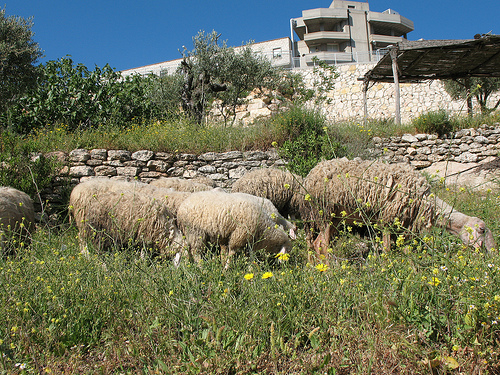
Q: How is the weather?
A: It is clear.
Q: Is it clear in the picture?
A: Yes, it is clear.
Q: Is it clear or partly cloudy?
A: It is clear.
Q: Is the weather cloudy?
A: No, it is clear.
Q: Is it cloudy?
A: No, it is clear.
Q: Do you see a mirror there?
A: No, there are no mirrors.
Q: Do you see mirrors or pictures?
A: No, there are no mirrors or pictures.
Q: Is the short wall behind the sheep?
A: Yes, the wall is behind the sheep.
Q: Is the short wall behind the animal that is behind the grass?
A: Yes, the wall is behind the sheep.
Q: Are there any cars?
A: No, there are no cars.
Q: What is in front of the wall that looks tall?
A: The trees are in front of the wall.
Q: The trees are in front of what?
A: The trees are in front of the wall.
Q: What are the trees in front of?
A: The trees are in front of the wall.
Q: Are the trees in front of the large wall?
A: Yes, the trees are in front of the wall.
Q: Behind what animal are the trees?
A: The trees are behind the sheep.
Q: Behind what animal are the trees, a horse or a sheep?
A: The trees are behind a sheep.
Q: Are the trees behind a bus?
A: No, the trees are behind the sheep.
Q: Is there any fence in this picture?
A: Yes, there is a fence.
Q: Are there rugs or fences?
A: Yes, there is a fence.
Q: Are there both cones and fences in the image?
A: No, there is a fence but no cones.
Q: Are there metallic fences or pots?
A: Yes, there is a metal fence.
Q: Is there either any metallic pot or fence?
A: Yes, there is a metal fence.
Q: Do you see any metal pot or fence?
A: Yes, there is a metal fence.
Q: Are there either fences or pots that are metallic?
A: Yes, the fence is metallic.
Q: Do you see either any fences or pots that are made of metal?
A: Yes, the fence is made of metal.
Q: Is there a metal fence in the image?
A: Yes, there is a metal fence.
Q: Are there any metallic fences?
A: Yes, there is a metal fence.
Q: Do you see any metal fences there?
A: Yes, there is a metal fence.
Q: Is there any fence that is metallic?
A: Yes, there is a fence that is metallic.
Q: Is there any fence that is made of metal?
A: Yes, there is a fence that is made of metal.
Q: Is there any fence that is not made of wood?
A: Yes, there is a fence that is made of metal.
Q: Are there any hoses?
A: No, there are no hoses.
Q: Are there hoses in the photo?
A: No, there are no hoses.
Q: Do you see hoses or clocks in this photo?
A: No, there are no hoses or clocks.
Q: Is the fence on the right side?
A: Yes, the fence is on the right of the image.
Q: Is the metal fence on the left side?
A: No, the fence is on the right of the image.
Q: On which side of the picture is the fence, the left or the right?
A: The fence is on the right of the image.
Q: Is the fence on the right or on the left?
A: The fence is on the right of the image.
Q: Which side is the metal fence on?
A: The fence is on the right of the image.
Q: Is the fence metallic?
A: Yes, the fence is metallic.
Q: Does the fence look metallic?
A: Yes, the fence is metallic.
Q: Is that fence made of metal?
A: Yes, the fence is made of metal.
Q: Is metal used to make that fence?
A: Yes, the fence is made of metal.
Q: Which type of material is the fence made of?
A: The fence is made of metal.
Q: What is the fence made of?
A: The fence is made of metal.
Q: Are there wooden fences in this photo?
A: No, there is a fence but it is metallic.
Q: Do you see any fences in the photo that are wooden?
A: No, there is a fence but it is metallic.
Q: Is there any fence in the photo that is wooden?
A: No, there is a fence but it is metallic.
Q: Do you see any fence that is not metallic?
A: No, there is a fence but it is metallic.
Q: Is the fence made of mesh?
A: No, the fence is made of metal.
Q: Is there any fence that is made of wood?
A: No, there is a fence but it is made of metal.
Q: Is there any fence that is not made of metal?
A: No, there is a fence but it is made of metal.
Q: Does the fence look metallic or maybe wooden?
A: The fence is metallic.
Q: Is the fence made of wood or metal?
A: The fence is made of metal.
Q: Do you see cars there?
A: No, there are no cars.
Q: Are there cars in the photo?
A: No, there are no cars.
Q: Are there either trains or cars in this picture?
A: No, there are no cars or trains.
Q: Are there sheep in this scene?
A: Yes, there is a sheep.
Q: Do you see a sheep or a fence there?
A: Yes, there is a sheep.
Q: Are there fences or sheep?
A: Yes, there is a sheep.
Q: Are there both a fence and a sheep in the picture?
A: Yes, there are both a sheep and a fence.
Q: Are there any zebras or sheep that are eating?
A: Yes, the sheep is eating.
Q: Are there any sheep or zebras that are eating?
A: Yes, the sheep is eating.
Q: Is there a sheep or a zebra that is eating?
A: Yes, the sheep is eating.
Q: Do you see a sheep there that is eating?
A: Yes, there is a sheep that is eating.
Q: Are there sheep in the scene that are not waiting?
A: Yes, there is a sheep that is eating.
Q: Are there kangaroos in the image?
A: No, there are no kangaroos.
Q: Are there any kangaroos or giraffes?
A: No, there are no kangaroos or giraffes.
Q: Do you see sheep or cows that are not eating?
A: No, there is a sheep but it is eating.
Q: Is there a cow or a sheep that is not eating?
A: No, there is a sheep but it is eating.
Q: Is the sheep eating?
A: Yes, the sheep is eating.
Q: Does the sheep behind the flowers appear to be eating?
A: Yes, the sheep is eating.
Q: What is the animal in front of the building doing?
A: The sheep is eating.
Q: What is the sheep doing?
A: The sheep is eating.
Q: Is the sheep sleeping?
A: No, the sheep is eating.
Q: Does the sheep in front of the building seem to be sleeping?
A: No, the sheep is eating.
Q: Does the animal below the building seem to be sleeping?
A: No, the sheep is eating.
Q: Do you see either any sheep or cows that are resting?
A: No, there is a sheep but it is eating.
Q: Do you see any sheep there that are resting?
A: No, there is a sheep but it is eating.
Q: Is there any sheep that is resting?
A: No, there is a sheep but it is eating.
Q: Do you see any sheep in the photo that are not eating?
A: No, there is a sheep but it is eating.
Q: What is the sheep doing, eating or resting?
A: The sheep is eating.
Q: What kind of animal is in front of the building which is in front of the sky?
A: The animal is a sheep.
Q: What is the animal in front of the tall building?
A: The animal is a sheep.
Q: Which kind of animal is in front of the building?
A: The animal is a sheep.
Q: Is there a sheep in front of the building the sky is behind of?
A: Yes, there is a sheep in front of the building.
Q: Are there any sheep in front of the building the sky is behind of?
A: Yes, there is a sheep in front of the building.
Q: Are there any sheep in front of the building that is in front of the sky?
A: Yes, there is a sheep in front of the building.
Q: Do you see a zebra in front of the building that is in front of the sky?
A: No, there is a sheep in front of the building.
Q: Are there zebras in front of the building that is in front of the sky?
A: No, there is a sheep in front of the building.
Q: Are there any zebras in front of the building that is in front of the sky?
A: No, there is a sheep in front of the building.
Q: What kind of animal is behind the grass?
A: The animal is a sheep.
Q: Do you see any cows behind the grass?
A: No, there is a sheep behind the grass.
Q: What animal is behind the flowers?
A: The animal is a sheep.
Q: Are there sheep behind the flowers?
A: Yes, there is a sheep behind the flowers.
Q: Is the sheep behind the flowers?
A: Yes, the sheep is behind the flowers.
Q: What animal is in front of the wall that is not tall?
A: The sheep is in front of the wall.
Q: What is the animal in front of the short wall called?
A: The animal is a sheep.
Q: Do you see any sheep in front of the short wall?
A: Yes, there is a sheep in front of the wall.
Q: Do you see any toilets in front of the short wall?
A: No, there is a sheep in front of the wall.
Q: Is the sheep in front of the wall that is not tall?
A: Yes, the sheep is in front of the wall.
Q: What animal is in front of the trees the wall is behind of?
A: The sheep is in front of the trees.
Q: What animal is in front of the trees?
A: The sheep is in front of the trees.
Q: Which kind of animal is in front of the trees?
A: The animal is a sheep.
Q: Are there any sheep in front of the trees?
A: Yes, there is a sheep in front of the trees.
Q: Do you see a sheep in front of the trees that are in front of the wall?
A: Yes, there is a sheep in front of the trees.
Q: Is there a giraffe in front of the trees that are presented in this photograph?
A: No, there is a sheep in front of the trees.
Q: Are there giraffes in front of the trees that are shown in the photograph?
A: No, there is a sheep in front of the trees.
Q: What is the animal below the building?
A: The animal is a sheep.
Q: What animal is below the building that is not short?
A: The animal is a sheep.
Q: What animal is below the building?
A: The animal is a sheep.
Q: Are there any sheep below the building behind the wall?
A: Yes, there is a sheep below the building.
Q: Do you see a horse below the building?
A: No, there is a sheep below the building.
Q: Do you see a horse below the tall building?
A: No, there is a sheep below the building.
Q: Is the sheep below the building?
A: Yes, the sheep is below the building.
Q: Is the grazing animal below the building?
A: Yes, the sheep is below the building.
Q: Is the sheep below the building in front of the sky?
A: Yes, the sheep is below the building.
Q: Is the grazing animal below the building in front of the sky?
A: Yes, the sheep is below the building.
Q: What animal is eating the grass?
A: The sheep is eating the grass.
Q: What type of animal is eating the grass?
A: The animal is a sheep.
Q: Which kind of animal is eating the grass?
A: The animal is a sheep.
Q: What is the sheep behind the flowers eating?
A: The sheep is eating grass.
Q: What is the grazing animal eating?
A: The sheep is eating grass.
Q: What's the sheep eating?
A: The sheep is eating grass.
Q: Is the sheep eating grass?
A: Yes, the sheep is eating grass.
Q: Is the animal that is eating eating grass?
A: Yes, the sheep is eating grass.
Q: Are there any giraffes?
A: No, there are no giraffes.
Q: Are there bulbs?
A: No, there are no bulbs.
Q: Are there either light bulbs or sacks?
A: No, there are no light bulbs or sacks.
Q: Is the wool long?
A: Yes, the wool is long.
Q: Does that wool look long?
A: Yes, the wool is long.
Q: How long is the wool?
A: The wool is long.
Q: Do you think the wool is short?
A: No, the wool is long.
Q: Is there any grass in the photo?
A: Yes, there is grass.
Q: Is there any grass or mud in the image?
A: Yes, there is grass.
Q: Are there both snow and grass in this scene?
A: No, there is grass but no snow.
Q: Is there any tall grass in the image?
A: Yes, there is tall grass.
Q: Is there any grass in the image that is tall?
A: Yes, there is grass that is tall.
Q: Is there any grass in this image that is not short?
A: Yes, there is tall grass.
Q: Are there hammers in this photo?
A: No, there are no hammers.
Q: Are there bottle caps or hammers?
A: No, there are no hammers or bottle caps.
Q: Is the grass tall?
A: Yes, the grass is tall.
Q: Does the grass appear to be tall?
A: Yes, the grass is tall.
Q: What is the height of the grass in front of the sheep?
A: The grass is tall.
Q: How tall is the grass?
A: The grass is tall.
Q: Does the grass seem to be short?
A: No, the grass is tall.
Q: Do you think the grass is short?
A: No, the grass is tall.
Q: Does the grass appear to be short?
A: No, the grass is tall.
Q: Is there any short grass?
A: No, there is grass but it is tall.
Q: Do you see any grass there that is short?
A: No, there is grass but it is tall.